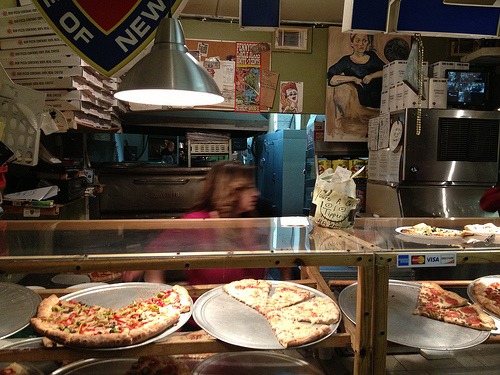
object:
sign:
[34, 0, 188, 79]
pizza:
[28, 284, 191, 348]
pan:
[192, 279, 343, 349]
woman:
[143, 159, 266, 333]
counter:
[0, 217, 500, 375]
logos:
[395, 251, 457, 269]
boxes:
[6, 65, 84, 89]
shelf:
[73, 131, 117, 141]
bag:
[308, 165, 361, 230]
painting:
[279, 80, 305, 113]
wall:
[307, 60, 320, 66]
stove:
[396, 108, 500, 218]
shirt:
[142, 209, 266, 286]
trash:
[321, 166, 354, 184]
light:
[114, 0, 226, 108]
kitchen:
[257, 113, 368, 218]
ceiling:
[317, 4, 333, 12]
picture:
[323, 25, 412, 142]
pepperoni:
[445, 296, 459, 305]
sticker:
[396, 250, 458, 268]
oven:
[396, 107, 500, 218]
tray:
[57, 281, 194, 352]